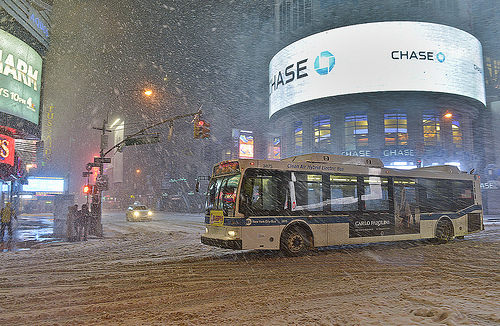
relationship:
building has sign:
[412, 123, 427, 164] [339, 23, 390, 89]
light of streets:
[127, 77, 154, 102] [102, 281, 178, 309]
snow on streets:
[156, 8, 175, 30] [102, 281, 178, 309]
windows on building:
[311, 114, 330, 149] [412, 123, 427, 164]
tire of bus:
[288, 231, 315, 257] [215, 158, 424, 245]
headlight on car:
[129, 210, 151, 222] [132, 206, 147, 223]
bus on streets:
[215, 158, 424, 245] [102, 281, 178, 309]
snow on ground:
[156, 8, 175, 30] [361, 246, 412, 298]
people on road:
[1, 192, 115, 243] [136, 275, 177, 310]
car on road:
[132, 206, 147, 223] [136, 275, 177, 310]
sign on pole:
[339, 23, 390, 89] [71, 179, 115, 219]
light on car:
[127, 77, 154, 102] [132, 206, 147, 223]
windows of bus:
[311, 114, 330, 149] [215, 158, 424, 245]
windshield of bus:
[204, 176, 243, 207] [215, 158, 424, 245]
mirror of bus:
[235, 195, 248, 222] [215, 158, 424, 245]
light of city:
[127, 77, 154, 102] [236, 3, 260, 38]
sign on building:
[339, 23, 390, 89] [412, 123, 427, 164]